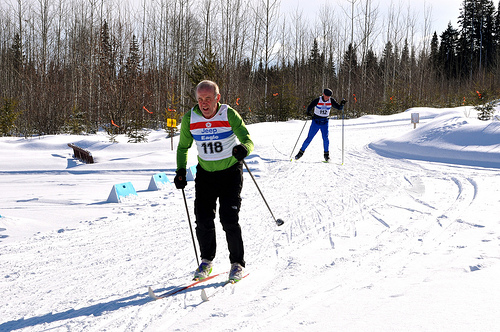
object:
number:
[200, 142, 224, 153]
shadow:
[1, 269, 237, 327]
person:
[178, 81, 256, 287]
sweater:
[175, 109, 253, 169]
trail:
[0, 108, 488, 332]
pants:
[194, 168, 246, 267]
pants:
[298, 119, 332, 154]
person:
[295, 86, 345, 160]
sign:
[167, 118, 175, 128]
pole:
[170, 128, 174, 152]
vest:
[189, 103, 240, 162]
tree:
[311, 39, 321, 117]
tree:
[337, 44, 364, 120]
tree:
[356, 53, 386, 118]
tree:
[380, 44, 400, 114]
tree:
[400, 44, 410, 105]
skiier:
[295, 86, 345, 160]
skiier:
[178, 81, 256, 287]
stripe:
[190, 130, 234, 141]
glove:
[231, 144, 247, 162]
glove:
[174, 168, 188, 189]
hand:
[231, 144, 249, 162]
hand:
[173, 167, 187, 189]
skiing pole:
[241, 158, 284, 226]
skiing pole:
[181, 187, 200, 267]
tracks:
[0, 160, 474, 331]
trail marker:
[106, 182, 139, 204]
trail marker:
[147, 172, 171, 192]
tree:
[438, 20, 461, 78]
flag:
[110, 120, 121, 128]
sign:
[410, 113, 421, 125]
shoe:
[227, 262, 245, 283]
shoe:
[193, 261, 212, 281]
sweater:
[306, 97, 343, 122]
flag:
[353, 94, 359, 104]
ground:
[0, 107, 500, 329]